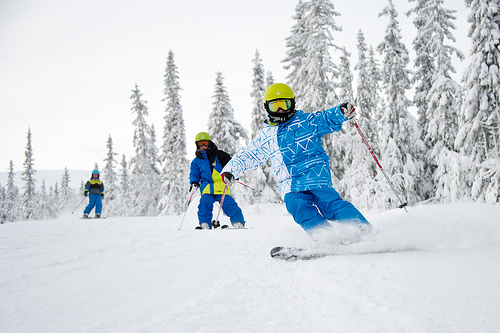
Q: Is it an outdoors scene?
A: Yes, it is outdoors.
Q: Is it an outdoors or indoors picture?
A: It is outdoors.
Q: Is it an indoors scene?
A: No, it is outdoors.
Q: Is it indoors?
A: No, it is outdoors.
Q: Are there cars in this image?
A: No, there are no cars.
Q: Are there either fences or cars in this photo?
A: No, there are no cars or fences.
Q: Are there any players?
A: No, there are no players.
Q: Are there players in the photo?
A: No, there are no players.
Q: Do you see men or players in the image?
A: No, there are no players or men.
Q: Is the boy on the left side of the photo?
A: Yes, the boy is on the left of the image.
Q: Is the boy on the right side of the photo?
A: No, the boy is on the left of the image.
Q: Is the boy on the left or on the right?
A: The boy is on the left of the image.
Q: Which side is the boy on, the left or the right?
A: The boy is on the left of the image.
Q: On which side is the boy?
A: The boy is on the left of the image.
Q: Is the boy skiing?
A: Yes, the boy is skiing.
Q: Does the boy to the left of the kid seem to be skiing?
A: Yes, the boy is skiing.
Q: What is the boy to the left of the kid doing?
A: The boy is skiing.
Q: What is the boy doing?
A: The boy is skiing.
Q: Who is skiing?
A: The boy is skiing.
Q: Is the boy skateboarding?
A: No, the boy is skiing.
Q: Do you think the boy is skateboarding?
A: No, the boy is skiing.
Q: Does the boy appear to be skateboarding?
A: No, the boy is skiing.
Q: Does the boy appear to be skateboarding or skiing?
A: The boy is skiing.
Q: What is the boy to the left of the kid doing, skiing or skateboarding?
A: The boy is skiing.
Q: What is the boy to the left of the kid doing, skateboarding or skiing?
A: The boy is skiing.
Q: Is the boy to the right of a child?
A: No, the boy is to the left of a child.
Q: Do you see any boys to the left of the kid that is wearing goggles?
A: Yes, there is a boy to the left of the kid.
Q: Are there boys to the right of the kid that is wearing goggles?
A: No, the boy is to the left of the kid.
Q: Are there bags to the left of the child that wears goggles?
A: No, there is a boy to the left of the kid.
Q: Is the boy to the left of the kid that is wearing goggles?
A: Yes, the boy is to the left of the kid.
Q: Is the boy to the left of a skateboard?
A: No, the boy is to the left of the kid.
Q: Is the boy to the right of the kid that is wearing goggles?
A: No, the boy is to the left of the kid.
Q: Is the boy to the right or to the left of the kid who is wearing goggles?
A: The boy is to the left of the kid.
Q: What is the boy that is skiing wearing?
A: The boy is wearing a helmet.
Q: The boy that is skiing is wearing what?
A: The boy is wearing a helmet.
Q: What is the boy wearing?
A: The boy is wearing a helmet.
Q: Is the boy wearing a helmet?
A: Yes, the boy is wearing a helmet.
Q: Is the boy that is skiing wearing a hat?
A: No, the boy is wearing a helmet.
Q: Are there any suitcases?
A: No, there are no suitcases.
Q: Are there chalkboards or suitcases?
A: No, there are no suitcases or chalkboards.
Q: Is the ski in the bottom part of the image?
A: Yes, the ski is in the bottom of the image.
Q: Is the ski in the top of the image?
A: No, the ski is in the bottom of the image.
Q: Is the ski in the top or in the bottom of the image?
A: The ski is in the bottom of the image.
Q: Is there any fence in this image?
A: No, there are no fences.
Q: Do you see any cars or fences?
A: No, there are no fences or cars.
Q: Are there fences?
A: No, there are no fences.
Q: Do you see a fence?
A: No, there are no fences.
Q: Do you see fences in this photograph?
A: No, there are no fences.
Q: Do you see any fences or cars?
A: No, there are no fences or cars.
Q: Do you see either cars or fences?
A: No, there are no fences or cars.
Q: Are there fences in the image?
A: No, there are no fences.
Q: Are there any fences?
A: No, there are no fences.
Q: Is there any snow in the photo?
A: Yes, there is snow.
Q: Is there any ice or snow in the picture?
A: Yes, there is snow.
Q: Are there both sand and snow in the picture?
A: No, there is snow but no sand.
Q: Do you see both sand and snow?
A: No, there is snow but no sand.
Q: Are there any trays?
A: No, there are no trays.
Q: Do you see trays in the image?
A: No, there are no trays.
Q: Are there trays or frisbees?
A: No, there are no trays or frisbees.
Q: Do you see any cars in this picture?
A: No, there are no cars.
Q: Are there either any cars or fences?
A: No, there are no cars or fences.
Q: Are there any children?
A: Yes, there is a child.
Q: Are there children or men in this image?
A: Yes, there is a child.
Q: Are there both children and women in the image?
A: No, there is a child but no women.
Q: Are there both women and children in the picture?
A: No, there is a child but no women.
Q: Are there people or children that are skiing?
A: Yes, the child is skiing.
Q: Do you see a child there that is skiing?
A: Yes, there is a child that is skiing.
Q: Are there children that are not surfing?
A: Yes, there is a child that is skiing.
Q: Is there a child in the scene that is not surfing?
A: Yes, there is a child that is skiing.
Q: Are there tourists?
A: No, there are no tourists.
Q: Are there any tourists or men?
A: No, there are no tourists or men.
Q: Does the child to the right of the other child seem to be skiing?
A: Yes, the kid is skiing.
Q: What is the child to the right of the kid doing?
A: The child is skiing.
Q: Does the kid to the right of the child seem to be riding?
A: No, the child is skiing.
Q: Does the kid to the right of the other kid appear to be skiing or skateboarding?
A: The kid is skiing.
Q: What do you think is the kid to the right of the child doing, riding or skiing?
A: The child is skiing.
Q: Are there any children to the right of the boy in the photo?
A: Yes, there is a child to the right of the boy.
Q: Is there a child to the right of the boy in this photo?
A: Yes, there is a child to the right of the boy.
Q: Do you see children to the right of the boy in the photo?
A: Yes, there is a child to the right of the boy.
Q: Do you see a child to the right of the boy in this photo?
A: Yes, there is a child to the right of the boy.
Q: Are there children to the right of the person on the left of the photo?
A: Yes, there is a child to the right of the boy.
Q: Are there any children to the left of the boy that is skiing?
A: No, the child is to the right of the boy.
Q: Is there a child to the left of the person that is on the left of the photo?
A: No, the child is to the right of the boy.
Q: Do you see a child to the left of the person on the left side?
A: No, the child is to the right of the boy.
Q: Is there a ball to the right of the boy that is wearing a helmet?
A: No, there is a child to the right of the boy.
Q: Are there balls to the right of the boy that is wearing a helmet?
A: No, there is a child to the right of the boy.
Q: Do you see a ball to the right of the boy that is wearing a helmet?
A: No, there is a child to the right of the boy.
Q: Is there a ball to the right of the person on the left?
A: No, there is a child to the right of the boy.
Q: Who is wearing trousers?
A: The child is wearing trousers.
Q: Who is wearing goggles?
A: The child is wearing goggles.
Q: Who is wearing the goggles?
A: The child is wearing goggles.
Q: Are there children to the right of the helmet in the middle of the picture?
A: Yes, there is a child to the right of the helmet.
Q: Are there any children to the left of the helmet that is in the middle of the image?
A: No, the child is to the right of the helmet.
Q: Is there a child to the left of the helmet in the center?
A: No, the child is to the right of the helmet.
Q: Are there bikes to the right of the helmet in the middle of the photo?
A: No, there is a child to the right of the helmet.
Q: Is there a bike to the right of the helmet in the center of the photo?
A: No, there is a child to the right of the helmet.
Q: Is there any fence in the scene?
A: No, there are no fences.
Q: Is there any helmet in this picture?
A: Yes, there is a helmet.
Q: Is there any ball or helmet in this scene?
A: Yes, there is a helmet.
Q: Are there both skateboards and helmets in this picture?
A: No, there is a helmet but no skateboards.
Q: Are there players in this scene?
A: No, there are no players.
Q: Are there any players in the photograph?
A: No, there are no players.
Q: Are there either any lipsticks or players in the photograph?
A: No, there are no players or lipsticks.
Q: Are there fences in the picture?
A: No, there are no fences.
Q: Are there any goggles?
A: Yes, there are goggles.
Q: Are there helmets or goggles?
A: Yes, there are goggles.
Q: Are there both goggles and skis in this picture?
A: Yes, there are both goggles and a ski.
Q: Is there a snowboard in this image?
A: No, there are no snowboards.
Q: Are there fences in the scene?
A: No, there are no fences.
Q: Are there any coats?
A: Yes, there is a coat.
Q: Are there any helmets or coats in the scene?
A: Yes, there is a coat.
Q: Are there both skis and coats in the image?
A: Yes, there are both a coat and skis.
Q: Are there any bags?
A: No, there are no bags.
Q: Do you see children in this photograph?
A: Yes, there is a child.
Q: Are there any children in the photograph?
A: Yes, there is a child.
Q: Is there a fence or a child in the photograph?
A: Yes, there is a child.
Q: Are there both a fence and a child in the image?
A: No, there is a child but no fences.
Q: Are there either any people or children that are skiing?
A: Yes, the child is skiing.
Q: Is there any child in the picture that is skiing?
A: Yes, there is a child that is skiing.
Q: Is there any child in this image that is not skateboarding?
A: Yes, there is a child that is skiing.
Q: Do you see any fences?
A: No, there are no fences.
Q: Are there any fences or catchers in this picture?
A: No, there are no fences or catchers.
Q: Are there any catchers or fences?
A: No, there are no fences or catchers.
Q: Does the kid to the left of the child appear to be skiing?
A: Yes, the child is skiing.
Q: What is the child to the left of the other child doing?
A: The child is skiing.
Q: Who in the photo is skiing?
A: The child is skiing.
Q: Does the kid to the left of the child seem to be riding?
A: No, the child is skiing.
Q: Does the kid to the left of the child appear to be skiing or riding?
A: The child is skiing.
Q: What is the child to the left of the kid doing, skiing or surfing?
A: The child is skiing.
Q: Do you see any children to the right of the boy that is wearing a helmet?
A: Yes, there is a child to the right of the boy.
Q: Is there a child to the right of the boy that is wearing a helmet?
A: Yes, there is a child to the right of the boy.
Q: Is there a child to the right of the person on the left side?
A: Yes, there is a child to the right of the boy.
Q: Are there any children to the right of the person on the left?
A: Yes, there is a child to the right of the boy.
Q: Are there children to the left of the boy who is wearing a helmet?
A: No, the child is to the right of the boy.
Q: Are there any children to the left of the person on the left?
A: No, the child is to the right of the boy.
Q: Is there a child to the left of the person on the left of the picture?
A: No, the child is to the right of the boy.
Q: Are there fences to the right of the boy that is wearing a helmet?
A: No, there is a child to the right of the boy.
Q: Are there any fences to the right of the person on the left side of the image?
A: No, there is a child to the right of the boy.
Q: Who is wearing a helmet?
A: The child is wearing a helmet.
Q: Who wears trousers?
A: The child wears trousers.